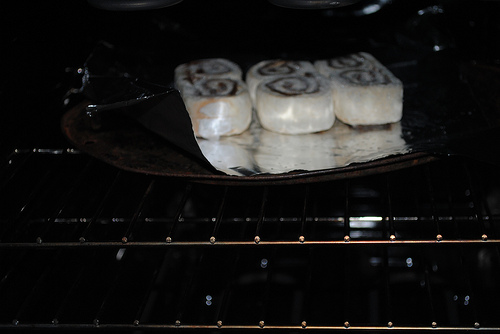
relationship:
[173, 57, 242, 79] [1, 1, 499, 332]
cinnamon roll in oven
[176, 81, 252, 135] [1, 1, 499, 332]
cinnamon roll in oven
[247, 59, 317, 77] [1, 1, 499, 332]
cinnamon roll in oven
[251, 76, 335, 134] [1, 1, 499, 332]
cinnamon roll in oven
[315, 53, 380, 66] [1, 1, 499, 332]
cinnamon roll in oven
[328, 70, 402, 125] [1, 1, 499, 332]
cinnamon roll in oven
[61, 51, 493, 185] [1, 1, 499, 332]
pan inside oven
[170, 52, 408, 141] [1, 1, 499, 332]
cinnamon rolls baking in oven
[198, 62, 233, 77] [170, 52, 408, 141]
design in middle of cinnamon rolls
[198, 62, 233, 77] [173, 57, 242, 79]
design in middle of cinnamon roll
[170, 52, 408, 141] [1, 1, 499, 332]
cinnamon rolls are baking inside oven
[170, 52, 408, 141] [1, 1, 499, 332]
cinnamon rolls baking inside oven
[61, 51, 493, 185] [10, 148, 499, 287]
pan on rack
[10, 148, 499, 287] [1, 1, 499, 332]
rack in oven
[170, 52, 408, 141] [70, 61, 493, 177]
cinnamon rolls are on top of foil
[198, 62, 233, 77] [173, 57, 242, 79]
design in cinnamon roll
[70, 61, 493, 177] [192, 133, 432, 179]
foil reflects reflection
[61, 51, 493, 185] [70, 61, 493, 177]
pan covered with foil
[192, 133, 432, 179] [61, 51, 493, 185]
reflection on pan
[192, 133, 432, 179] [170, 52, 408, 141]
reflection of cinnamon rolls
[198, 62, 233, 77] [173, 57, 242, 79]
swirl in cinnamon roll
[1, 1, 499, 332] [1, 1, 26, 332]
oven has wall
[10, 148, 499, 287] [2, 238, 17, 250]
rack has spoke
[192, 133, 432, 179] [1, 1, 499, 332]
reflection in oven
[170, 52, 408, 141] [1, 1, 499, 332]
cinnamon rolls in oven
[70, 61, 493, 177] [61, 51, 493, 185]
foil on pan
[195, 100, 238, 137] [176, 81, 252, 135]
orange on cinnamon roll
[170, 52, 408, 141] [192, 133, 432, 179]
cinnamon rolls make reflection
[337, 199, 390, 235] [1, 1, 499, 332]
spot in oven